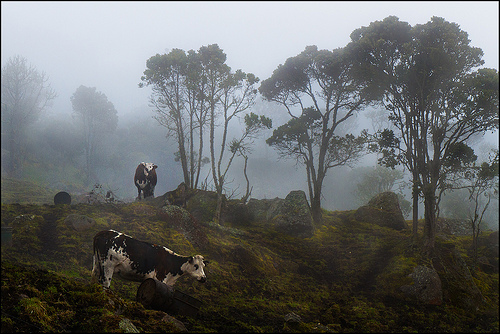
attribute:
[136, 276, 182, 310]
barrel — sitting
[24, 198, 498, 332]
hillside — rocky, foggy, mossy, green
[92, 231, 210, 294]
cow — black, white, standing, full-grown, spotted, grazing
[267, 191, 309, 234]
rock — large, mossy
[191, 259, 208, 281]
face — white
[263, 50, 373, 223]
tree — tall, leafy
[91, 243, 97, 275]
tail — black, white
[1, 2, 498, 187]
sky — foggy, white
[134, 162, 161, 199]
cow — standing, black, white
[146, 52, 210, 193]
tree — tall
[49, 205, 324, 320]
grass — green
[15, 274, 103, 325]
moss — green, thick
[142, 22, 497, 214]
trees — green, thin